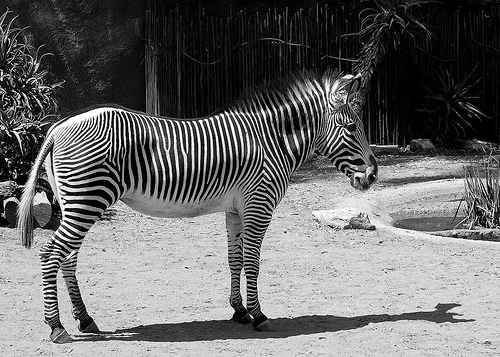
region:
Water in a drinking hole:
[417, 217, 449, 227]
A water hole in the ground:
[409, 190, 446, 210]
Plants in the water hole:
[471, 187, 488, 222]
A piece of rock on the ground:
[326, 209, 361, 224]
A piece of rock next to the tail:
[35, 200, 46, 219]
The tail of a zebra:
[22, 204, 29, 240]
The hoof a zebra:
[52, 332, 69, 340]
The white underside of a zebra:
[164, 208, 187, 215]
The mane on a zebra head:
[321, 71, 339, 78]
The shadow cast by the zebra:
[292, 318, 338, 328]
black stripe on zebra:
[44, 293, 56, 304]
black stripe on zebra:
[43, 288, 58, 295]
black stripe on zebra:
[42, 270, 59, 280]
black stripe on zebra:
[48, 235, 68, 253]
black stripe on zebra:
[53, 232, 82, 252]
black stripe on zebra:
[58, 221, 81, 240]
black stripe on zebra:
[63, 210, 93, 224]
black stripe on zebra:
[61, 195, 105, 208]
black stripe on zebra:
[56, 187, 115, 204]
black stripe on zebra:
[281, 103, 303, 165]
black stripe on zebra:
[335, 155, 364, 167]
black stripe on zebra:
[330, 148, 355, 162]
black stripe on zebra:
[43, 285, 56, 290]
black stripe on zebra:
[65, 220, 85, 231]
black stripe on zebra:
[63, 205, 104, 219]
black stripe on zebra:
[69, 170, 108, 185]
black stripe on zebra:
[327, 140, 359, 158]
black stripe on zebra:
[41, 270, 57, 280]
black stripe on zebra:
[65, 215, 90, 233]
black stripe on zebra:
[306, 92, 323, 131]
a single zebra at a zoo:
[20, 69, 385, 336]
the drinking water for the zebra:
[348, 146, 498, 260]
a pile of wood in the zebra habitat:
[5, 179, 60, 230]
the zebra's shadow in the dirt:
[66, 291, 474, 345]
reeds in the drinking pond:
[453, 144, 498, 242]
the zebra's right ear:
[325, 72, 350, 109]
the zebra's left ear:
[345, 72, 364, 106]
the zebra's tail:
[12, 121, 50, 248]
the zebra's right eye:
[340, 119, 357, 134]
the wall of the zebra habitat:
[138, 9, 411, 156]